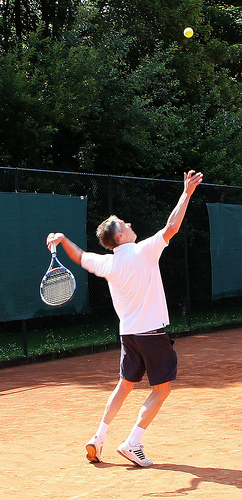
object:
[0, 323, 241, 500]
tennis court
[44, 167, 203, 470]
man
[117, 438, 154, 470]
tennis shoes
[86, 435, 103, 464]
tennis shoes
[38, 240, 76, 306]
tennis racket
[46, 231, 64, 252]
left hand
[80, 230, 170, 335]
shirt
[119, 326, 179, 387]
shorts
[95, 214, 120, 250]
hair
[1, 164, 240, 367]
fence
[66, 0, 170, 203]
trees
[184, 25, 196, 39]
tennis ball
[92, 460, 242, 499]
shadow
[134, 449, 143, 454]
lines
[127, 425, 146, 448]
socks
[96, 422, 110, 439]
socks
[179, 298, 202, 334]
weed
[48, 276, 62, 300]
strings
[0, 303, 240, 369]
grass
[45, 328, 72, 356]
plant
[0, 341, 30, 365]
plant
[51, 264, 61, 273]
middle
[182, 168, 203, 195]
hand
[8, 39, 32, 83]
leaves